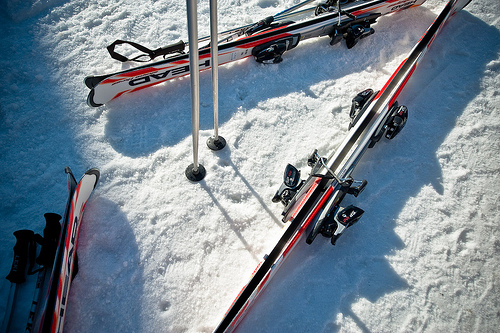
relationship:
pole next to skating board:
[209, 0, 219, 149] [207, 0, 475, 332]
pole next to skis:
[209, 0, 219, 149] [85, 0, 429, 139]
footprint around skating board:
[440, 222, 477, 263] [207, 0, 475, 332]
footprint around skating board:
[453, 271, 490, 329] [207, 0, 475, 332]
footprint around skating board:
[401, 282, 438, 331] [207, 0, 475, 332]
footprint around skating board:
[396, 225, 423, 263] [207, 0, 475, 332]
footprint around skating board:
[491, 255, 498, 305] [207, 0, 475, 332]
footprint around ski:
[440, 222, 477, 263] [217, 0, 454, 331]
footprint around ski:
[453, 271, 490, 329] [217, 0, 454, 331]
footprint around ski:
[401, 282, 438, 331] [217, 0, 454, 331]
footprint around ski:
[396, 225, 423, 263] [217, 0, 454, 331]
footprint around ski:
[491, 255, 498, 305] [217, 0, 454, 331]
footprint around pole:
[440, 222, 477, 263] [204, 0, 229, 154]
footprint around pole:
[453, 271, 490, 329] [204, 0, 229, 154]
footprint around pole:
[401, 282, 438, 331] [204, 0, 229, 154]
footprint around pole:
[396, 225, 423, 263] [204, 0, 229, 154]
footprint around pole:
[491, 255, 498, 305] [204, 0, 229, 154]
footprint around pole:
[440, 222, 477, 263] [180, 0, 207, 186]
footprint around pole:
[453, 271, 490, 329] [180, 0, 207, 186]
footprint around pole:
[401, 282, 438, 331] [180, 0, 207, 186]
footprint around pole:
[396, 225, 423, 263] [180, 0, 207, 186]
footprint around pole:
[491, 255, 498, 305] [180, 0, 207, 186]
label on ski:
[123, 57, 214, 89] [80, 2, 425, 105]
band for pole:
[110, 34, 154, 64] [97, 0, 336, 67]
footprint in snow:
[139, 216, 199, 278] [1, 0, 497, 331]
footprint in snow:
[233, 116, 285, 181] [1, 0, 497, 331]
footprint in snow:
[87, 181, 139, 236] [1, 0, 497, 331]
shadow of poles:
[198, 179, 276, 244] [165, 4, 245, 194]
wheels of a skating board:
[173, 134, 237, 181] [69, 4, 416, 96]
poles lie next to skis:
[186, 2, 219, 181] [77, 1, 387, 106]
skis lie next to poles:
[77, 1, 387, 106] [186, 2, 219, 181]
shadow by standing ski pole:
[180, 183, 256, 264] [184, 2, 203, 180]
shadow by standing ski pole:
[180, 183, 256, 264] [205, 1, 225, 148]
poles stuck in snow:
[186, 0, 207, 180] [157, 180, 260, 257]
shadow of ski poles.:
[238, 165, 279, 219] [207, 2, 232, 147]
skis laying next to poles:
[77, 0, 431, 106] [1, 205, 46, 322]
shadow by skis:
[105, 44, 364, 150] [89, 39, 323, 73]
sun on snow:
[137, 171, 207, 240] [1, 0, 497, 331]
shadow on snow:
[15, 58, 120, 236] [81, 101, 413, 301]